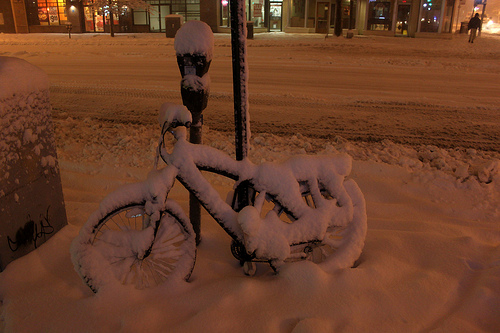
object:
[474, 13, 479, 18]
head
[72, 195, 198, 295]
wheel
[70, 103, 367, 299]
bicycle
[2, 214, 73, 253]
graffiti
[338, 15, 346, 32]
pole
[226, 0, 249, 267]
metal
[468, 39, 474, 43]
shoes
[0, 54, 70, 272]
block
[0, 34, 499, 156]
street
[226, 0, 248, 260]
post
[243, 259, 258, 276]
pedal part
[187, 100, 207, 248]
pole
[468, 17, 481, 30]
black coat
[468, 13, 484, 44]
person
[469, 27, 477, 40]
legs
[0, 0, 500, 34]
shops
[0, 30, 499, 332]
snow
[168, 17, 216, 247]
meter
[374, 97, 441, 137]
ground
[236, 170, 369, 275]
back wheel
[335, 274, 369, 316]
ground